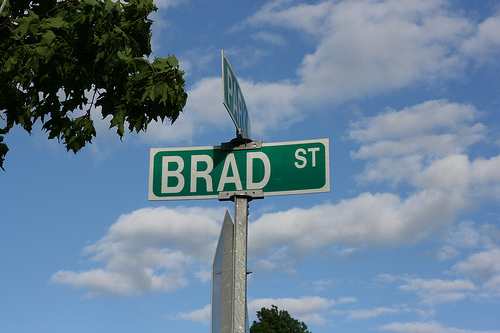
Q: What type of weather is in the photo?
A: It is cloudy.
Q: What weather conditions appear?
A: It is cloudy.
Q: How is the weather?
A: It is cloudy.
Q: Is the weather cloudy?
A: Yes, it is cloudy.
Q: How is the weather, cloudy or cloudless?
A: It is cloudy.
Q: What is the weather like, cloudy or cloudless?
A: It is cloudy.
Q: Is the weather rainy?
A: No, it is cloudy.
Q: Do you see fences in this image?
A: No, there are no fences.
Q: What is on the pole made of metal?
A: The sign is on the pole.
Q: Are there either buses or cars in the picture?
A: No, there are no cars or buses.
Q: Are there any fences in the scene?
A: No, there are no fences.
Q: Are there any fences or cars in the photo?
A: No, there are no fences or cars.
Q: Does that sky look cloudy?
A: Yes, the sky is cloudy.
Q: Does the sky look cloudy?
A: Yes, the sky is cloudy.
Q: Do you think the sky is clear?
A: No, the sky is cloudy.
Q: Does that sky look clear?
A: No, the sky is cloudy.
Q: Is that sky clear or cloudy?
A: The sky is cloudy.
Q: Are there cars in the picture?
A: No, there are no cars.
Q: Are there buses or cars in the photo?
A: No, there are no cars or buses.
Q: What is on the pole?
A: The sign is on the pole.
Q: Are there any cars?
A: No, there are no cars.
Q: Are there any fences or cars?
A: No, there are no cars or fences.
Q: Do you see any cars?
A: No, there are no cars.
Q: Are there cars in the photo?
A: No, there are no cars.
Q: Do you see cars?
A: No, there are no cars.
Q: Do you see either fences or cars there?
A: No, there are no cars or fences.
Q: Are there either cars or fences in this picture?
A: No, there are no cars or fences.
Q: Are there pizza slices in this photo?
A: No, there are no pizza slices.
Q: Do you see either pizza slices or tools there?
A: No, there are no pizza slices or tools.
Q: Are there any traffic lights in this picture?
A: No, there are no traffic lights.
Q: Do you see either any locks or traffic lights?
A: No, there are no traffic lights or locks.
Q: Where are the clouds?
A: The clouds are in the sky.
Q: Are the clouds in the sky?
A: Yes, the clouds are in the sky.